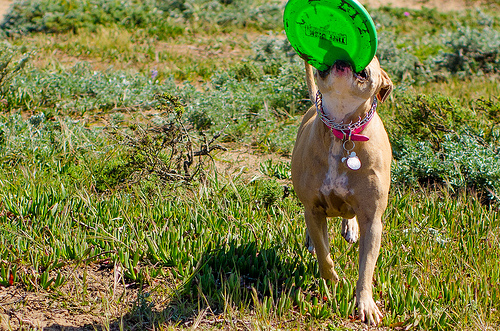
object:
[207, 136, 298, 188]
lines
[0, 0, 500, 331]
picture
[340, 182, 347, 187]
?